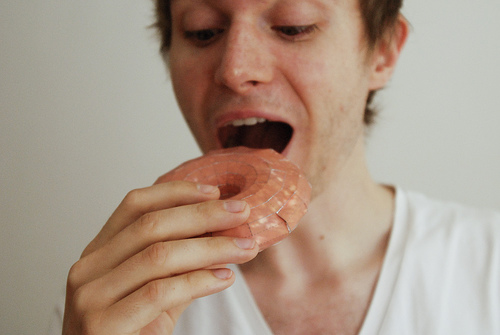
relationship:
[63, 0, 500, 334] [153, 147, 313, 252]
man eating donut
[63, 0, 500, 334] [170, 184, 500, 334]
man wearing shirt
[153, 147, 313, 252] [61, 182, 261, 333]
donut in hand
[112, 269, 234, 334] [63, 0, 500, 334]
pinky of man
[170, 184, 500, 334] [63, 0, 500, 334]
shirt on man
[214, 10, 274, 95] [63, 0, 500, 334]
nose of man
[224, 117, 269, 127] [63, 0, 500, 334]
teeth of man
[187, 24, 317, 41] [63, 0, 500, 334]
eyes of man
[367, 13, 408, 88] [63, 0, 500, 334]
ear of man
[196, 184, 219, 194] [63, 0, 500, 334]
nail on man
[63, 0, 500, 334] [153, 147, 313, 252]
man holding donut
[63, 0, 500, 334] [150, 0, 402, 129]
man has hair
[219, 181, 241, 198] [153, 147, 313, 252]
hole of donut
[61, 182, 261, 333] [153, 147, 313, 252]
hand holding donut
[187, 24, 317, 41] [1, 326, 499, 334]
eyes looking down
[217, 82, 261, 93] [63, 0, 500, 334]
nostrils of man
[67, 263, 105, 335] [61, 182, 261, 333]
knuckles of hand